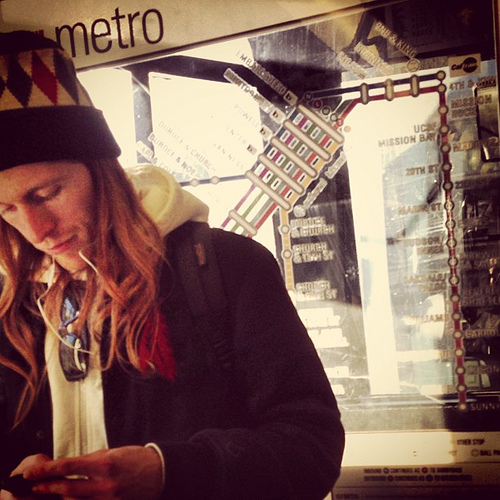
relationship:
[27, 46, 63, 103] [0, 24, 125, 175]
diamond on cap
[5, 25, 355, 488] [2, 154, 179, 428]
man has hair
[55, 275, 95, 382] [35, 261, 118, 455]
sunglasses hanging on front of sweatshirt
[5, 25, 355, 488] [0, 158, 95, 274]
man has face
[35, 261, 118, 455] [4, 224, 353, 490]
sweatshirt under jacket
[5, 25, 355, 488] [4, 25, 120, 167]
man wearing hat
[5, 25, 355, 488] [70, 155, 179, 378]
man has hair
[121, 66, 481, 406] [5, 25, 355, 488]
mirror behind man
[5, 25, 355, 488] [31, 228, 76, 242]
man has mustache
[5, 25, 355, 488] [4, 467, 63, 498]
man looking at cell phone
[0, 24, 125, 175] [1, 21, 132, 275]
cap on head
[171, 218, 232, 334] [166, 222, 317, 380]
strap on shoulder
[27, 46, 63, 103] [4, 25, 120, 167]
diamond on hat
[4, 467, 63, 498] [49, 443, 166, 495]
cell phone in hand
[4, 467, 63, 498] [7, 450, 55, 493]
cell phone in hand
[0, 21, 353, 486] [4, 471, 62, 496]
man on cell phone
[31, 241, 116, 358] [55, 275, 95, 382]
headphone cords in front of sunglasses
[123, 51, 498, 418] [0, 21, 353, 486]
metro map behind man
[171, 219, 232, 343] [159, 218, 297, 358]
strap on shoulder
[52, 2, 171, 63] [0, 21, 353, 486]
word above man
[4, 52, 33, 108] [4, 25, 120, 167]
diamond on hat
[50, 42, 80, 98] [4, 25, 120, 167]
diamond on hat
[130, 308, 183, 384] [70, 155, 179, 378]
feathers hanging from hair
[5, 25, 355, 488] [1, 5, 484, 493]
man in subway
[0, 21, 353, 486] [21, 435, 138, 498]
man with cell phone